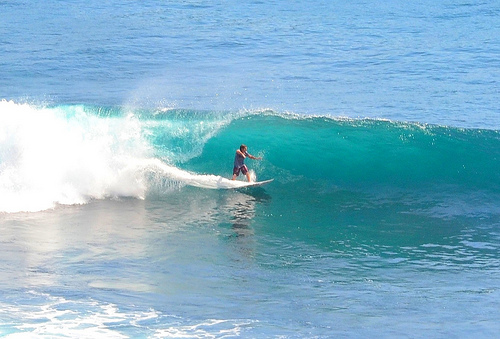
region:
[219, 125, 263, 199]
surfer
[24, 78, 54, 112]
blue and white waves in ocean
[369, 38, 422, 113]
blue and white waves in ocean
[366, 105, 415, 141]
blue and white waves in ocean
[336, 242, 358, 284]
blue and white waves in ocean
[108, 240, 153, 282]
blue and white waves in ocean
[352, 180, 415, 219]
blue and white waves in ocean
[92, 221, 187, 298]
blue and white waves in ocean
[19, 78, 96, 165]
blue and white waves in ocean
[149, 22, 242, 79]
blue and white waves in ocean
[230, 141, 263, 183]
a surfer riding a wave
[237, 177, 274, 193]
a surfboard under the person's feet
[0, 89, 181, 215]
splashing water from the wave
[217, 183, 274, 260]
the reflection of the surfer in the water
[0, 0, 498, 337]
a vast blue ocean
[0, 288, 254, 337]
foam on the top of the water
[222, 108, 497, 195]
a part of the wave that is still forming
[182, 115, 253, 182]
the inner tubular part of the wave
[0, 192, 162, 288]
a reflection of the wave in the water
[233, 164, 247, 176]
a pair of long shorts on the surfer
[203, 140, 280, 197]
guy on surf board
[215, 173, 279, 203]
white surf board in water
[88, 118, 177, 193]
large wave in water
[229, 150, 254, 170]
blue shirt on man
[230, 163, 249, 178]
swim shorts on man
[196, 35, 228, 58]
small ripples of water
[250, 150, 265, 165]
extended hand of man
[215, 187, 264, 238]
reflection of man surfing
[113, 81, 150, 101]
light water mist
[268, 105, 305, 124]
top of a wave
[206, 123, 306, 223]
the surfer is surfing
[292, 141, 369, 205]
the water is bluegreen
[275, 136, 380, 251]
the water is bluegreen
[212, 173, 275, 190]
Man standing on a board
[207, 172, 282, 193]
Man is standing on a board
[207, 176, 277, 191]
Man standing on a white board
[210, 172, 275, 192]
Man is standing on a white board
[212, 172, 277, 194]
Man standing on a surfboard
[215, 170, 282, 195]
Man is standing on a surfboard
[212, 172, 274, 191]
Man standing on a white surfboard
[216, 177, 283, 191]
Man is standing on a white surfboard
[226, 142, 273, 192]
Man riding a white surfboard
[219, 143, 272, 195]
Man is riding a surfboard